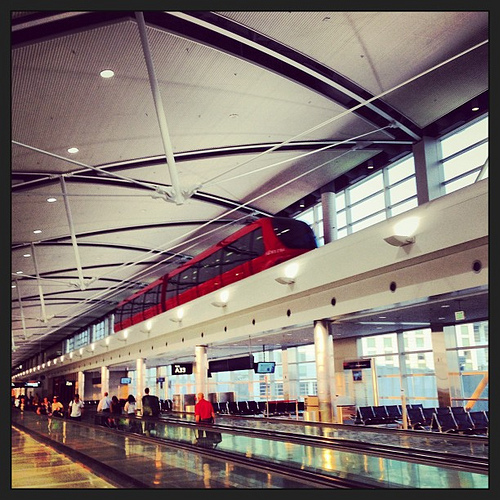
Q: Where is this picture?
A: Train station.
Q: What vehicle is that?
A: Train.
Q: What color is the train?
A: Red.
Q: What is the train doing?
A: Moving.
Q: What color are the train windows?
A: Black.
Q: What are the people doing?
A: Walking.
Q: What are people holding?
A: Luggage.